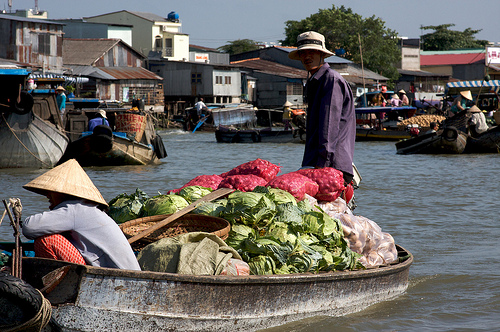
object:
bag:
[272, 171, 320, 202]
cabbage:
[228, 192, 271, 226]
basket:
[121, 212, 231, 249]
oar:
[125, 185, 235, 243]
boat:
[5, 237, 413, 331]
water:
[2, 131, 498, 332]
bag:
[319, 195, 399, 268]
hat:
[287, 31, 337, 56]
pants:
[34, 233, 85, 265]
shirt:
[304, 62, 356, 183]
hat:
[24, 158, 110, 208]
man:
[290, 31, 356, 201]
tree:
[280, 5, 401, 90]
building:
[62, 38, 163, 128]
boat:
[2, 109, 68, 170]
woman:
[22, 156, 143, 273]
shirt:
[21, 203, 141, 270]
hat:
[398, 90, 404, 93]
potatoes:
[398, 114, 446, 131]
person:
[168, 10, 179, 22]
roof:
[95, 66, 162, 80]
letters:
[118, 115, 144, 132]